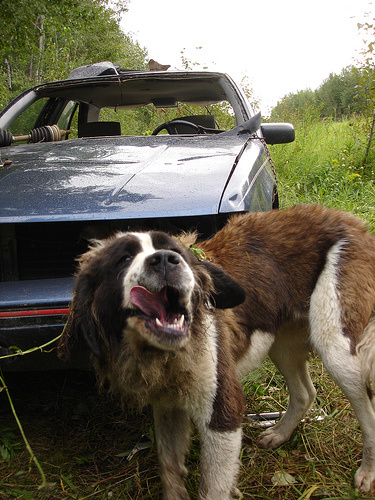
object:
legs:
[342, 385, 374, 462]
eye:
[118, 251, 138, 265]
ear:
[199, 261, 246, 311]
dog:
[58, 200, 375, 500]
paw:
[256, 421, 287, 452]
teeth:
[154, 317, 163, 329]